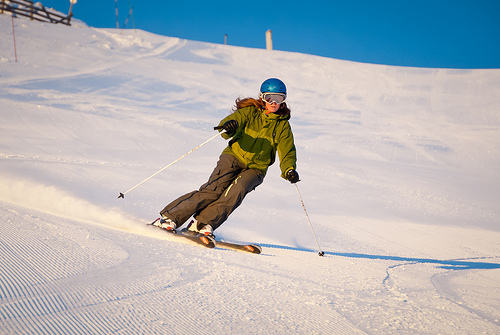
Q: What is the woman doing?
A: Skiing.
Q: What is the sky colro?
A: Blue.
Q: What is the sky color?
A: Blue.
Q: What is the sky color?
A: Blue.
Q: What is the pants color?
A: Black.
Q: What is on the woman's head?
A: A blue helmet.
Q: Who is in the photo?
A: A woman .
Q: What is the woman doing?
A: Skiing downhill.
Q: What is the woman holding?
A: Ski poles.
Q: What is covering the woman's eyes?
A: Ski goggles.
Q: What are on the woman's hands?
A: Black gloves.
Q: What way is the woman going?
A: Downhill.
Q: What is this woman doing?
A: Skiing.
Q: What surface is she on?
A: Snow.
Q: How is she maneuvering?
A: Ski poles.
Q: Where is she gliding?
A: Down a slope.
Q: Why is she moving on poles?
A: To ski.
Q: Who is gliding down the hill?
A: A woman.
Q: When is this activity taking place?
A: Morning.